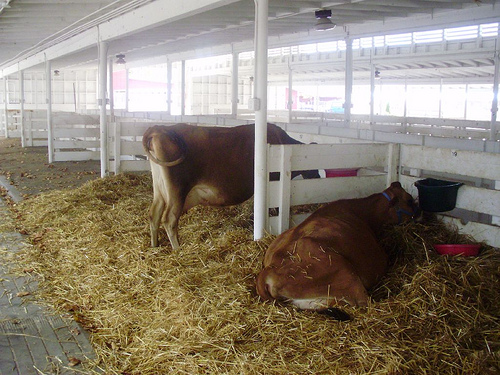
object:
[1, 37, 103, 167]
stalls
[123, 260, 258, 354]
straw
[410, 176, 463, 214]
container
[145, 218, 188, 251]
feet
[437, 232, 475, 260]
pan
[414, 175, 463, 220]
bucket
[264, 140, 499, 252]
fence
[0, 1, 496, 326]
stalls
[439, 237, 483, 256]
red bowl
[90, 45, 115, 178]
pole structure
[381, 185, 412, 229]
blue strap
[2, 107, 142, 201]
back part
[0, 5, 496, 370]
cow pen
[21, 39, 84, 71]
white ceiling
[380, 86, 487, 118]
window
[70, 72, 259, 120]
windows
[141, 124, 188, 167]
tail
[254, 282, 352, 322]
tail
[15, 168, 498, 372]
hay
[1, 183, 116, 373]
walkway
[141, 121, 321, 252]
cow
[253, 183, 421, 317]
cow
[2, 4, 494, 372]
barn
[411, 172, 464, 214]
dish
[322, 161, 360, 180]
dish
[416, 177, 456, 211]
plastic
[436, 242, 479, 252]
plastic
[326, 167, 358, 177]
plastic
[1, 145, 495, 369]
ground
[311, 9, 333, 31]
light fixtures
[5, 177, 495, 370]
front part